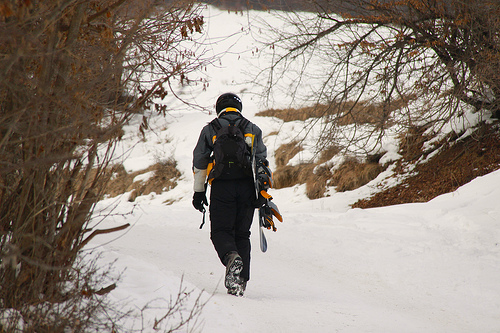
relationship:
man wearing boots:
[193, 78, 270, 286] [224, 255, 255, 299]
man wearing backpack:
[193, 78, 270, 286] [225, 123, 276, 181]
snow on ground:
[375, 282, 403, 295] [246, 73, 286, 94]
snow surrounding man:
[375, 282, 403, 295] [193, 78, 270, 286]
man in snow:
[193, 78, 270, 286] [375, 282, 403, 295]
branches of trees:
[104, 6, 150, 24] [371, 33, 469, 117]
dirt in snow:
[270, 104, 298, 116] [375, 282, 403, 295]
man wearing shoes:
[193, 78, 270, 286] [229, 283, 257, 295]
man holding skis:
[193, 78, 270, 286] [195, 212, 205, 227]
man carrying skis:
[193, 78, 270, 286] [195, 212, 205, 227]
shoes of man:
[229, 283, 257, 295] [193, 78, 270, 286]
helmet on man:
[218, 92, 240, 110] [193, 78, 270, 286]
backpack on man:
[225, 123, 276, 181] [193, 78, 270, 286]